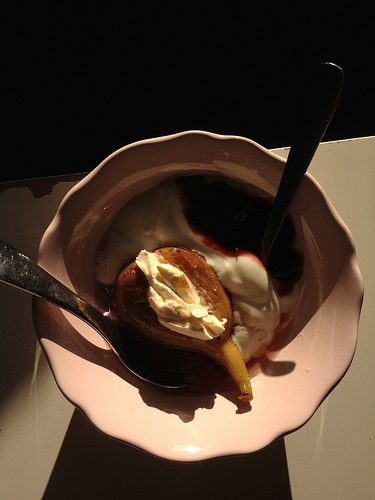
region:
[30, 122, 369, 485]
dessert in bowl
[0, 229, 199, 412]
metal spoon in bowl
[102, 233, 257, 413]
dried fruit in bowl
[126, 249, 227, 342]
whtie cream on top of dried fruit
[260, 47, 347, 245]
utensil in bowl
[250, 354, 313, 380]
black shadow on side of bowl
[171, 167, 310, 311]
sauce inside of bowl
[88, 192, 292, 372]
ice cream in bowl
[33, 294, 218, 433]
shadow of spoon in bowl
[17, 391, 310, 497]
black shadow on table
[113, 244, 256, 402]
A fig in bowl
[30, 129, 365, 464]
A pink desert bowl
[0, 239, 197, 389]
A metal spoon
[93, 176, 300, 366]
White yogurt in bowl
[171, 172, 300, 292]
Red berry sauce in bowl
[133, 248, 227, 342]
White filling inside of fig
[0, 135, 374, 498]
A painted white table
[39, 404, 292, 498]
Shadow of bowl on table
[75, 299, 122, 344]
Reflection of fig on spoon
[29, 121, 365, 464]
A white dish on the table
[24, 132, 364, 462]
A white dish with food in it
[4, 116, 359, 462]
A white dish with a spoon in it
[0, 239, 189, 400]
A silver spoon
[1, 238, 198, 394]
A silver eating utensil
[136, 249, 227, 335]
A dallop of cool whip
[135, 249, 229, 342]
A dallop of whip cream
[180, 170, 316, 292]
A flavored sauce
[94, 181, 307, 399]
A type of dessert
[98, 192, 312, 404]
A dessert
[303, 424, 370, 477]
A white table surface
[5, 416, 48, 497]
A white table surface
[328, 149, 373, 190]
A white table surface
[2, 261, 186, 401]
A small silver spoon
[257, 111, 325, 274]
A small silver spoon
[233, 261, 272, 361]
A white cream in a plate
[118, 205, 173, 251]
A white cream in a plate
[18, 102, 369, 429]
a bowl of food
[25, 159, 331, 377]
a glass bowl of food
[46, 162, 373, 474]
a glass bowl of ice cream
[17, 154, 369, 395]
two spoons in a bowl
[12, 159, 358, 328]
two silver spoons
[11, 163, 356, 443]
a bowl with spoons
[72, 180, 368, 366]
a bowl with fruit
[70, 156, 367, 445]
ice cream with toppings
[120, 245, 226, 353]
butter in the bowl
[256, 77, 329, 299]
a spoon in the bowl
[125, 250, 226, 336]
A piece of food.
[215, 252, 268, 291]
A piece of food.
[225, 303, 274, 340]
A piece of food.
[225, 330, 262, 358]
A piece of food.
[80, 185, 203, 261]
A piece of food.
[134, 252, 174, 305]
A piece of food.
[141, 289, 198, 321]
A piece of food.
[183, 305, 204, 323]
A piece of food.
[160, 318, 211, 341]
A piece of food.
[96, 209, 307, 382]
Food in white bowl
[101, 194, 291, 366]
Food in round bowl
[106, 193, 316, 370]
Food in white round bowl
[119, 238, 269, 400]
Fruit in the bowl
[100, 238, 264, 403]
Fruit in white bowl